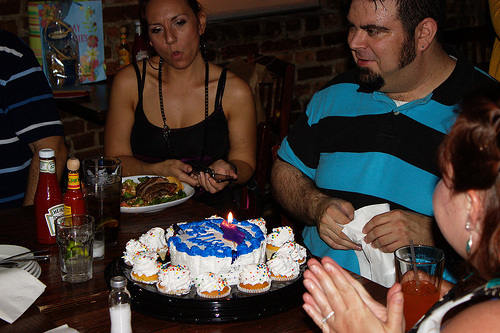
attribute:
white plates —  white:
[0, 245, 45, 287]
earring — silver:
[461, 217, 485, 260]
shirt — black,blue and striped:
[276, 75, 464, 298]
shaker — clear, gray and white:
[95, 276, 160, 331]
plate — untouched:
[117, 170, 197, 215]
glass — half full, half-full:
[391, 241, 446, 331]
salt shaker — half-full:
[108, 278, 133, 331]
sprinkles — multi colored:
[159, 264, 189, 279]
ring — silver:
[323, 306, 340, 327]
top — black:
[119, 69, 245, 154]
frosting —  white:
[180, 254, 262, 333]